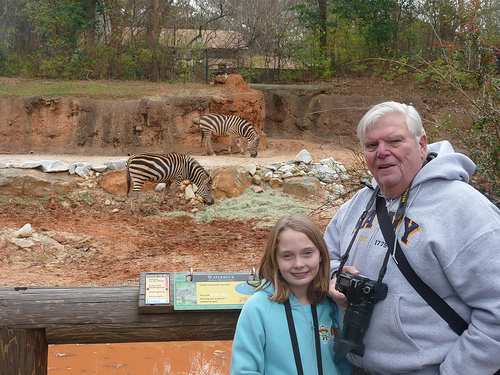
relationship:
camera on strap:
[334, 182, 409, 359] [335, 182, 408, 279]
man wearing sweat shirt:
[325, 101, 500, 374] [321, 140, 497, 375]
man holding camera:
[325, 101, 500, 374] [334, 182, 409, 359]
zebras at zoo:
[124, 112, 262, 215] [4, 4, 495, 233]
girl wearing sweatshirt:
[232, 218, 344, 375] [230, 285, 349, 375]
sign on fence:
[139, 266, 261, 315] [2, 284, 269, 375]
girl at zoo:
[232, 218, 344, 375] [4, 4, 495, 233]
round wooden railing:
[0, 278, 246, 374] [1, 285, 247, 341]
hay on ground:
[134, 207, 255, 259] [5, 138, 373, 268]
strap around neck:
[277, 291, 325, 375] [284, 280, 319, 307]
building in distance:
[113, 21, 249, 77] [8, 31, 500, 96]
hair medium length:
[251, 213, 332, 308] [254, 219, 333, 311]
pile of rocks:
[243, 146, 350, 186] [222, 139, 344, 187]